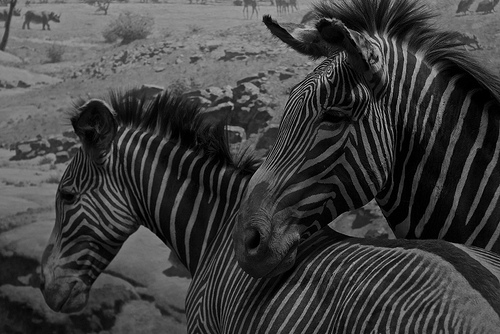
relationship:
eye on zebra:
[318, 92, 353, 132] [228, 0, 498, 271]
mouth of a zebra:
[248, 243, 304, 280] [222, 12, 499, 283]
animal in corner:
[4, 5, 57, 34] [0, 1, 107, 75]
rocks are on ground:
[198, 78, 281, 140] [2, 0, 499, 267]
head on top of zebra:
[231, 13, 396, 279] [31, 79, 494, 331]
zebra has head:
[228, 0, 498, 271] [231, 13, 396, 279]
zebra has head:
[228, 0, 498, 271] [234, 6, 396, 290]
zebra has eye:
[228, 0, 498, 271] [312, 107, 356, 132]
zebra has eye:
[228, 0, 498, 271] [314, 108, 344, 124]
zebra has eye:
[31, 79, 494, 331] [59, 190, 76, 205]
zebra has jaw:
[228, 0, 498, 271] [269, 183, 343, 285]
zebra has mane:
[31, 79, 494, 331] [109, 76, 279, 174]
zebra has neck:
[31, 79, 494, 331] [116, 142, 290, 308]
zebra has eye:
[228, 0, 498, 271] [297, 88, 365, 148]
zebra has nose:
[228, 0, 498, 271] [229, 199, 316, 286]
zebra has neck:
[228, 0, 498, 271] [389, 60, 499, 237]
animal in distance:
[14, 4, 65, 36] [1, 4, 494, 45]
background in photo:
[169, 10, 244, 40] [0, 0, 496, 331]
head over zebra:
[225, 1, 402, 282] [31, 79, 494, 331]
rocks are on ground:
[75, 30, 200, 97] [6, 2, 483, 325]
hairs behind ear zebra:
[106, 83, 261, 170] [313, 17, 391, 90]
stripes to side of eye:
[282, 103, 412, 198] [313, 97, 354, 134]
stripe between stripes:
[307, 129, 344, 162] [146, 136, 267, 303]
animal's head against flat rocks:
[37, 100, 144, 312] [1, 125, 186, 332]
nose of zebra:
[233, 180, 318, 274] [232, 2, 498, 299]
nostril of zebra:
[237, 222, 264, 256] [232, 2, 498, 299]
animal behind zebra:
[19, 9, 61, 32] [228, 0, 498, 271]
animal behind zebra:
[19, 9, 61, 32] [31, 79, 494, 331]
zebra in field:
[228, 0, 498, 271] [6, 7, 308, 157]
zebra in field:
[31, 79, 494, 331] [6, 7, 308, 157]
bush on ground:
[94, 15, 177, 67] [35, 30, 131, 90]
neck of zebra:
[128, 124, 245, 264] [29, 118, 498, 325]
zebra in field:
[228, 0, 498, 271] [1, 4, 498, 326]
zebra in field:
[31, 79, 494, 331] [1, 4, 498, 326]